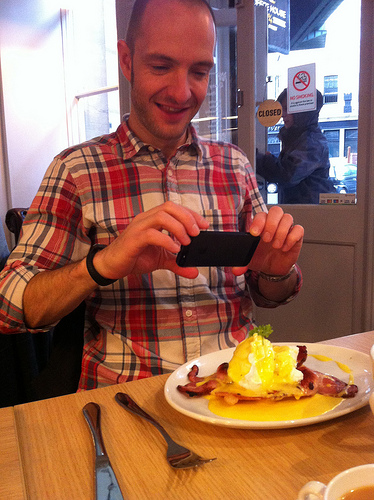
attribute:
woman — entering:
[253, 85, 340, 199]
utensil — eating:
[81, 401, 122, 498]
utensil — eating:
[114, 392, 217, 468]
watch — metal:
[260, 264, 297, 282]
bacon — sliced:
[169, 348, 236, 402]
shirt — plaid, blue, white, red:
[2, 114, 302, 391]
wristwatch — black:
[75, 246, 120, 288]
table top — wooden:
[1, 328, 372, 498]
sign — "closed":
[253, 93, 286, 140]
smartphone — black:
[174, 228, 259, 267]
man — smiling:
[13, 7, 310, 363]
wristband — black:
[74, 239, 113, 289]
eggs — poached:
[218, 336, 362, 383]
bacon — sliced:
[164, 337, 360, 397]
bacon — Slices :
[177, 364, 339, 414]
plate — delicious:
[163, 341, 362, 430]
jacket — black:
[253, 116, 337, 202]